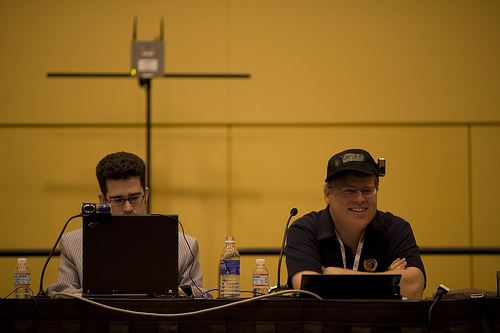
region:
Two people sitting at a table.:
[0, 145, 497, 332]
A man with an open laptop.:
[40, 149, 212, 302]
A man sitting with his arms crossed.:
[277, 144, 427, 300]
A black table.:
[0, 290, 499, 332]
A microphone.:
[273, 201, 301, 295]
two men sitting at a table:
[58, 139, 427, 295]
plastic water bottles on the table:
[8, 230, 274, 297]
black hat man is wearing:
[318, 145, 379, 183]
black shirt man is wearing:
[283, 209, 426, 293]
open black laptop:
[72, 212, 179, 294]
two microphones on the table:
[30, 205, 302, 308]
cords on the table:
[33, 277, 485, 330]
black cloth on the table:
[7, 293, 494, 332]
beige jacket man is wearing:
[51, 225, 205, 292]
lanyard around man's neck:
[332, 231, 362, 272]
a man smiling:
[253, 117, 457, 313]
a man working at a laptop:
[37, 135, 204, 324]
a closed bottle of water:
[245, 238, 279, 318]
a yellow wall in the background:
[12, 10, 497, 290]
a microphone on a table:
[264, 185, 306, 310]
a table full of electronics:
[0, 279, 487, 331]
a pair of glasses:
[88, 185, 169, 220]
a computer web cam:
[80, 200, 112, 215]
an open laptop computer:
[81, 213, 176, 295]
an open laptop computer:
[300, 272, 399, 299]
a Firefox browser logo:
[361, 255, 378, 272]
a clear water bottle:
[13, 256, 30, 296]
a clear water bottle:
[251, 256, 269, 296]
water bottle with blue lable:
[215, 232, 242, 298]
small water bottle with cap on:
[248, 255, 274, 295]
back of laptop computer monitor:
[73, 200, 183, 297]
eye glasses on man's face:
[101, 190, 151, 206]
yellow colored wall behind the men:
[296, 25, 478, 144]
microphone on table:
[273, 203, 301, 297]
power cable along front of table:
[64, 290, 261, 322]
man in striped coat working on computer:
[33, 141, 227, 301]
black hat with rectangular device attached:
[317, 141, 394, 184]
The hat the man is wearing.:
[327, 148, 385, 173]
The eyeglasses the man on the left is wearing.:
[111, 193, 143, 205]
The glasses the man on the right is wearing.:
[332, 184, 376, 194]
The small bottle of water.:
[248, 254, 267, 295]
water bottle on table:
[216, 235, 243, 297]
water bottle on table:
[251, 255, 270, 294]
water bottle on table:
[13, 257, 31, 292]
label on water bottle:
[14, 272, 33, 285]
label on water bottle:
[217, 257, 239, 274]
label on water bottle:
[252, 270, 270, 288]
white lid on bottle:
[254, 256, 265, 264]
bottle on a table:
[251, 250, 271, 300]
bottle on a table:
[210, 221, 241, 301]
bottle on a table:
[6, 245, 31, 300]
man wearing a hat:
[290, 147, 430, 297]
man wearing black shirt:
[291, 145, 434, 308]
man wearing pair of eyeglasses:
[65, 132, 195, 294]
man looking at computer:
[65, 151, 205, 301]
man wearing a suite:
[75, 145, 201, 290]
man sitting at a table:
[277, 145, 432, 300]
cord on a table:
[118, 304, 206, 317]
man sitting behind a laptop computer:
[44, 125, 186, 292]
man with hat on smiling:
[261, 121, 432, 303]